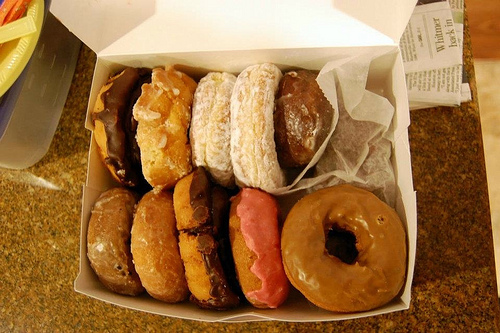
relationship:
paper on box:
[317, 60, 397, 184] [48, 0, 418, 324]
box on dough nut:
[48, 0, 418, 324] [173, 179, 232, 300]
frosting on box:
[90, 64, 150, 189] [48, 0, 418, 324]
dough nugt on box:
[126, 63, 188, 186] [48, 3, 422, 332]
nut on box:
[275, 69, 328, 168] [48, 3, 422, 332]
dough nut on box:
[187, 60, 235, 187] [48, 3, 422, 332]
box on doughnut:
[48, 3, 422, 332] [279, 182, 406, 308]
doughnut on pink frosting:
[227, 187, 286, 310] [230, 182, 282, 308]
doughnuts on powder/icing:
[186, 55, 284, 197] [189, 62, 285, 190]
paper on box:
[278, 60, 396, 205] [48, 3, 422, 332]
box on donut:
[48, 0, 418, 324] [279, 187, 404, 306]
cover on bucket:
[0, 74, 22, 137] [0, 10, 81, 172]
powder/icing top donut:
[189, 60, 285, 189] [190, 69, 235, 187]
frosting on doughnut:
[90, 64, 150, 189] [89, 78, 143, 187]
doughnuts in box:
[229, 62, 284, 191] [48, 3, 422, 332]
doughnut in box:
[227, 187, 286, 310] [48, 3, 422, 332]